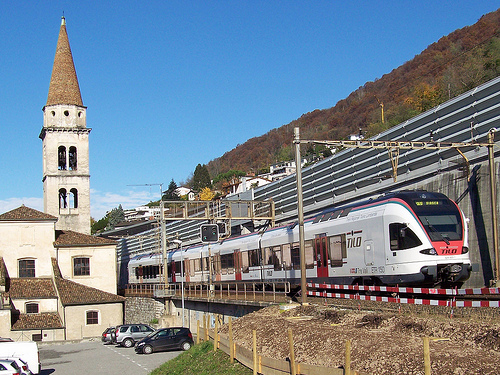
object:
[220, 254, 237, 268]
window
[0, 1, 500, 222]
sky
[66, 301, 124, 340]
wall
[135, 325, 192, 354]
car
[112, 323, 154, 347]
car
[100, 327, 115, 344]
car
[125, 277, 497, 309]
tracks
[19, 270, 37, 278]
window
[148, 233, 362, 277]
windows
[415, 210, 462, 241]
window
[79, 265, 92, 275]
window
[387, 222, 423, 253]
window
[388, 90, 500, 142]
lines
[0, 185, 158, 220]
clouds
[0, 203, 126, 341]
building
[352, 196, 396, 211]
red stripe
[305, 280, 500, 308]
notice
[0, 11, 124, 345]
church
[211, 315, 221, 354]
posts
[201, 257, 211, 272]
window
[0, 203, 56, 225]
roof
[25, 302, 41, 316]
window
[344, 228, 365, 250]
logo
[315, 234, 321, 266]
window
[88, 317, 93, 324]
window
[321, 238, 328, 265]
window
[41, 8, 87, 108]
steeple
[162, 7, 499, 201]
mountain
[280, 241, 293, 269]
window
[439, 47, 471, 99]
tree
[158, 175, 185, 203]
tree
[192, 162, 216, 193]
tree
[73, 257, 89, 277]
window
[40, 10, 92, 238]
building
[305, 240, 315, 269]
window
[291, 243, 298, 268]
window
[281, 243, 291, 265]
window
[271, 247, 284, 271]
window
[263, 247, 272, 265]
window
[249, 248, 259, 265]
window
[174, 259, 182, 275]
window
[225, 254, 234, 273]
window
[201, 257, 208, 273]
window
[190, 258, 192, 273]
window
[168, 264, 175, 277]
window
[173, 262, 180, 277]
window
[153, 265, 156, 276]
window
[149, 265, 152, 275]
window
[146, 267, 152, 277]
window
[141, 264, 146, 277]
window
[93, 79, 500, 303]
building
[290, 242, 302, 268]
window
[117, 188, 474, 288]
train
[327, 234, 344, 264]
window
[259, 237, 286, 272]
window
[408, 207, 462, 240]
windshield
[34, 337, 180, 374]
ground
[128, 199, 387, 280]
right side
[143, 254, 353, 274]
windows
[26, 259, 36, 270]
window